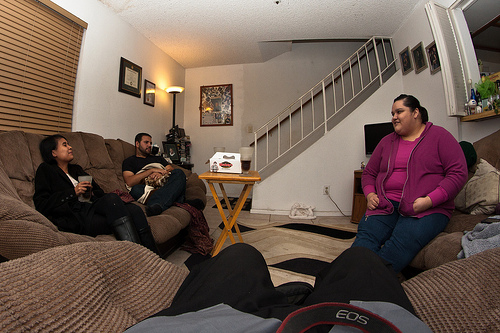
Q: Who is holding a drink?
A: Woman sitting on couch.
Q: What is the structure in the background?
A: Stairs.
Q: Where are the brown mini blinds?
A: On the window.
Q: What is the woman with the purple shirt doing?
A: Sitting.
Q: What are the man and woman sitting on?
A: Brown couch.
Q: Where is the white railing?
A: Along the stairway.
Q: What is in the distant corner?
A: Floor lamp.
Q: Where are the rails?
A: On the stairs.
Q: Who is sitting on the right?
A: Woman in purple hoodie.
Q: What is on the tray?
A: White box of food.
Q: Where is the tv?
A: Near the staircase.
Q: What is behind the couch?
A: A window.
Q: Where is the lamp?
A: In the corner.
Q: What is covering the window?
A: Brown blinds.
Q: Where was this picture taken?
A: The living room.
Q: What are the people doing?
A: Talking.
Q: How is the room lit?
A: The lamp.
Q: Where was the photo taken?
A: Living room.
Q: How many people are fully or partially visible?
A: Four.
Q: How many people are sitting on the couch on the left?
A: Two.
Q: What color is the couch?
A: Brown.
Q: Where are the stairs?
A: At the back of the picture.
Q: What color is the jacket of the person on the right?
A: Purple.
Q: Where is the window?
A: Behind the woman on the left.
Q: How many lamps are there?
A: One.